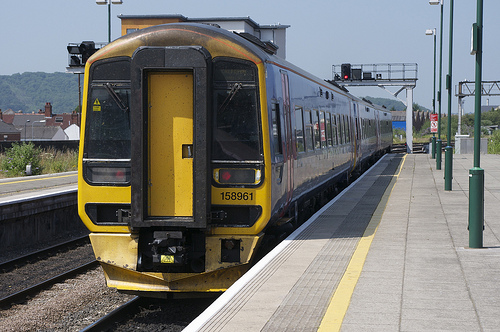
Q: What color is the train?
A: Yellow.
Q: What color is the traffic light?
A: Red.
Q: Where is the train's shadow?
A: To the right.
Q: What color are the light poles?
A: Green.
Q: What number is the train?
A: 158961.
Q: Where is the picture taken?
A: Train stop.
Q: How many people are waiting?
A: Zero.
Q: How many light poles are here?
A: Five.